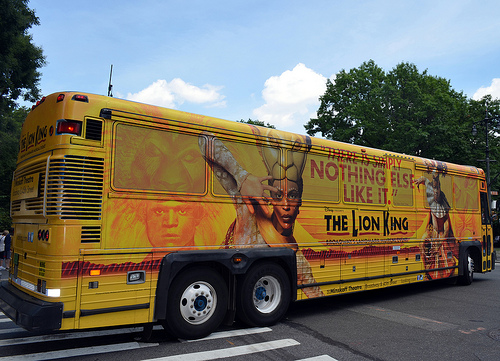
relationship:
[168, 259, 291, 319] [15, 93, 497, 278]
wheels on bus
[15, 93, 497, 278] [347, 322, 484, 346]
bus on road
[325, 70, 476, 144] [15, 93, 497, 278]
trees by bus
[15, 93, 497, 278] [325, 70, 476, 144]
bus by trees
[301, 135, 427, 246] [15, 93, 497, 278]
ad on bus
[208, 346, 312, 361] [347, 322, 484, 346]
lines on road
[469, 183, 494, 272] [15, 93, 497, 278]
doors on bus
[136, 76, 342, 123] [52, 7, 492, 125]
clouds in sky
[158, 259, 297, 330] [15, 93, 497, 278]
wheels on bus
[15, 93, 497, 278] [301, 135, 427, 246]
bus has ad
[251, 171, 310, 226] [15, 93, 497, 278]
face on bus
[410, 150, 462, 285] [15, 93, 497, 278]
animal on bus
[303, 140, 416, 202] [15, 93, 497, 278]
red on bus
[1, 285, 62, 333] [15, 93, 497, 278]
back of bus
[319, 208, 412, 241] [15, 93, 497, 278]
black on bus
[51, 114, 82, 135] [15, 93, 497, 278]
lights on bus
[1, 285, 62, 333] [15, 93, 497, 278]
bumper on bus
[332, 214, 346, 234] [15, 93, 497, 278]
letter on bus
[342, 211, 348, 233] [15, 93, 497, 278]
e on bus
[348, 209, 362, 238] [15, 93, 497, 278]
l on bus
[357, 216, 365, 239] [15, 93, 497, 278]
i on bus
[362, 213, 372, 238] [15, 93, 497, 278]
o on bus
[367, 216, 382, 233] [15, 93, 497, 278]
n on bus